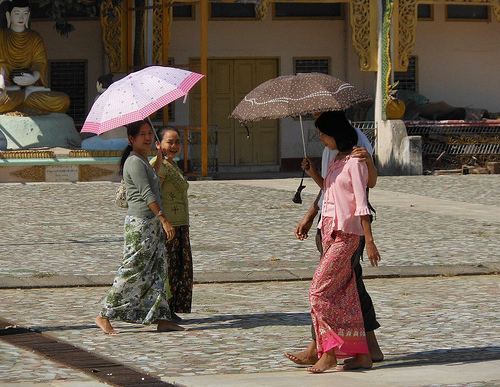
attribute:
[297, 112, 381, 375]
woman — barefoot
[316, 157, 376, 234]
sweater — pink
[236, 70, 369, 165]
umbrella — brown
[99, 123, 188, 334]
woman — barefoot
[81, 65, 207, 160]
umbrella — pink, white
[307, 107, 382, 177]
man — barefoot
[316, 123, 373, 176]
shirt — white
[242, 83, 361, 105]
design — white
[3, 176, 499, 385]
street — brick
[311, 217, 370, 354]
skirt — long, pink, patterned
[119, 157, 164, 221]
jacket — green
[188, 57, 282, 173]
door — yellow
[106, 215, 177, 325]
skirt — green, patterned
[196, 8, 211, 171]
pole — yellow